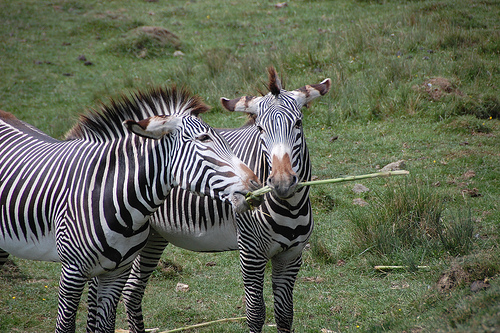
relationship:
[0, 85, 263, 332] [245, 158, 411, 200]
zebra fighting over branch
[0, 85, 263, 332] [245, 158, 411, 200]
zebra bitting on branch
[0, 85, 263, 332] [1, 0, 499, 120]
zebra in field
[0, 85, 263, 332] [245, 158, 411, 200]
zebra pulling branch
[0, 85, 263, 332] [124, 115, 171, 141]
zebra have ear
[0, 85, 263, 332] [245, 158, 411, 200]
zebra share branch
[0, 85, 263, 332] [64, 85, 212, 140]
zebra has mane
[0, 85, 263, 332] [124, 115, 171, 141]
zebra pointed ear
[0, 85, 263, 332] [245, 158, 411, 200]
zebra holds branch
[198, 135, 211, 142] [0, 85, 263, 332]
eye of zebra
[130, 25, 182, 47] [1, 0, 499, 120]
rock in field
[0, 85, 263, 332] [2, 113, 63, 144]
zebra back stripes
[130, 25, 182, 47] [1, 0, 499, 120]
rock on field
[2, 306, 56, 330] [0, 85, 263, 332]
grass beneath zebra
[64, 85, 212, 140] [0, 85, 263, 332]
mane of zebra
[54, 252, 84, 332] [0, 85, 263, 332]
leg of zebra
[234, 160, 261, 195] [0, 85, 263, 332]
nose of zebra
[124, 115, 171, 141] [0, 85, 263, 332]
ear of zebra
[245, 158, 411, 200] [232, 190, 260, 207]
branch in zebra mouth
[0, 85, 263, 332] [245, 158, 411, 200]
zebra eating branch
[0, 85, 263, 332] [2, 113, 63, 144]
zebra has stripes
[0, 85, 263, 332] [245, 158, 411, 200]
zebra chewing branch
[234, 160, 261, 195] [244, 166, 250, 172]
nose top brown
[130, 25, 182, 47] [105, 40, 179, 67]
rock behind grass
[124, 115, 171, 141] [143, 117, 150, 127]
ear top brown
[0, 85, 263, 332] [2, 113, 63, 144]
zebra dark stripes